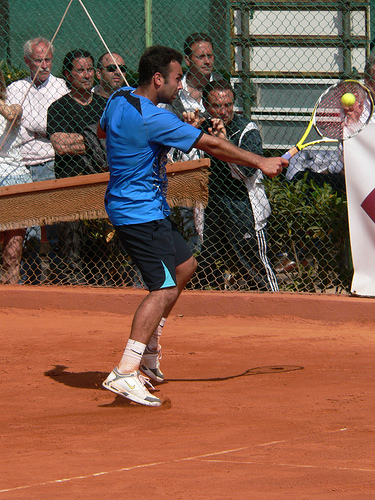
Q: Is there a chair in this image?
A: No, there are no chairs.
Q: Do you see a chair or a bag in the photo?
A: No, there are no chairs or bags.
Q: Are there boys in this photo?
A: No, there are no boys.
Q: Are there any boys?
A: No, there are no boys.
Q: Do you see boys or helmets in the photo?
A: No, there are no boys or helmets.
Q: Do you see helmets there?
A: No, there are no helmets.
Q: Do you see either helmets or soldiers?
A: No, there are no helmets or soldiers.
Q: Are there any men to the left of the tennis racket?
A: Yes, there is a man to the left of the tennis racket.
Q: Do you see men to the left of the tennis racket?
A: Yes, there is a man to the left of the tennis racket.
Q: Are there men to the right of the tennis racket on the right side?
A: No, the man is to the left of the racket.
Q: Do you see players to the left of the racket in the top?
A: No, there is a man to the left of the racket.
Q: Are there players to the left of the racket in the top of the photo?
A: No, there is a man to the left of the racket.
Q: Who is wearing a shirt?
A: The man is wearing a shirt.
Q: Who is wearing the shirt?
A: The man is wearing a shirt.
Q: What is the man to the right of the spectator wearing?
A: The man is wearing a shirt.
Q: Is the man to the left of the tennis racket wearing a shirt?
A: Yes, the man is wearing a shirt.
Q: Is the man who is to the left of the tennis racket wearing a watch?
A: No, the man is wearing a shirt.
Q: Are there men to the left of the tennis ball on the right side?
A: Yes, there is a man to the left of the tennis ball.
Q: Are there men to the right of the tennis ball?
A: No, the man is to the left of the tennis ball.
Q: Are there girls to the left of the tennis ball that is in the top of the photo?
A: No, there is a man to the left of the tennis ball.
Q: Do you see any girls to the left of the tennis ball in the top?
A: No, there is a man to the left of the tennis ball.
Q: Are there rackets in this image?
A: Yes, there is a racket.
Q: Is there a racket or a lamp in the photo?
A: Yes, there is a racket.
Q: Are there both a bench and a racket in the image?
A: No, there is a racket but no benches.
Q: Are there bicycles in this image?
A: No, there are no bicycles.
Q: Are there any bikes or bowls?
A: No, there are no bikes or bowls.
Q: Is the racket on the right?
A: Yes, the racket is on the right of the image.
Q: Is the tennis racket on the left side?
A: No, the tennis racket is on the right of the image.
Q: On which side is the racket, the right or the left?
A: The racket is on the right of the image.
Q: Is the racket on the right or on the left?
A: The racket is on the right of the image.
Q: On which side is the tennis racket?
A: The tennis racket is on the right of the image.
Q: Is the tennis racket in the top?
A: Yes, the tennis racket is in the top of the image.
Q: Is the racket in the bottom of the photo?
A: No, the racket is in the top of the image.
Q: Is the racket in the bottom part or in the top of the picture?
A: The racket is in the top of the image.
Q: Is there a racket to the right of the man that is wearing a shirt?
A: Yes, there is a racket to the right of the man.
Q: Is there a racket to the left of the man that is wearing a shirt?
A: No, the racket is to the right of the man.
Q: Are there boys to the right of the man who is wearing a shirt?
A: No, there is a racket to the right of the man.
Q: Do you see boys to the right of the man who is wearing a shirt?
A: No, there is a racket to the right of the man.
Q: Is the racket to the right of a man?
A: Yes, the racket is to the right of a man.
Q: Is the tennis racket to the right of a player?
A: No, the tennis racket is to the right of a man.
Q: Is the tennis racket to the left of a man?
A: No, the tennis racket is to the right of a man.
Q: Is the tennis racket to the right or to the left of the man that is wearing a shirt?
A: The tennis racket is to the right of the man.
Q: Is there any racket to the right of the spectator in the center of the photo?
A: Yes, there is a racket to the right of the spectator.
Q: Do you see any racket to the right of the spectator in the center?
A: Yes, there is a racket to the right of the spectator.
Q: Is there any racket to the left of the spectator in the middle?
A: No, the racket is to the right of the spectator.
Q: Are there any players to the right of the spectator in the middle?
A: No, there is a racket to the right of the spectator.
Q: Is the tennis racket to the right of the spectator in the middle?
A: Yes, the tennis racket is to the right of the spectator.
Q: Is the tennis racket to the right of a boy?
A: No, the tennis racket is to the right of the spectator.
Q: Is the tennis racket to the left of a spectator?
A: No, the tennis racket is to the right of a spectator.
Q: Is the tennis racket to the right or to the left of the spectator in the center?
A: The tennis racket is to the right of the spectator.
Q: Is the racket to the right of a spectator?
A: Yes, the racket is to the right of a spectator.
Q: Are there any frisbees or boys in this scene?
A: No, there are no boys or frisbees.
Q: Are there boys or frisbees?
A: No, there are no boys or frisbees.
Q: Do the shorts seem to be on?
A: Yes, the shorts are on.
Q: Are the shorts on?
A: Yes, the shorts are on.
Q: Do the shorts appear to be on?
A: Yes, the shorts are on.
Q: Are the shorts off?
A: No, the shorts are on.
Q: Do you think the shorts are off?
A: No, the shorts are on.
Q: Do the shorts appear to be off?
A: No, the shorts are on.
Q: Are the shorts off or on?
A: The shorts are on.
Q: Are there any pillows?
A: No, there are no pillows.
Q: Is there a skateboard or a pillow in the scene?
A: No, there are no pillows or skateboards.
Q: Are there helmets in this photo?
A: No, there are no helmets.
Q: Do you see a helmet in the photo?
A: No, there are no helmets.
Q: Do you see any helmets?
A: No, there are no helmets.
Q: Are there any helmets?
A: No, there are no helmets.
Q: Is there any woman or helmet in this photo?
A: No, there are no helmets or women.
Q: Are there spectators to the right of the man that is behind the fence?
A: Yes, there is a spectator to the right of the man.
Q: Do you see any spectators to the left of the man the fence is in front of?
A: No, the spectator is to the right of the man.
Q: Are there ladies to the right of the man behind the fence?
A: No, there is a spectator to the right of the man.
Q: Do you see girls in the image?
A: No, there are no girls.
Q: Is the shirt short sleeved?
A: Yes, the shirt is short sleeved.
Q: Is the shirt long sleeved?
A: No, the shirt is short sleeved.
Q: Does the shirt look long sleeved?
A: No, the shirt is short sleeved.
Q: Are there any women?
A: No, there are no women.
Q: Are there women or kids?
A: No, there are no women or kids.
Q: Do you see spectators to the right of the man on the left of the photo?
A: Yes, there is a spectator to the right of the man.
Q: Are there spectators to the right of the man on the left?
A: Yes, there is a spectator to the right of the man.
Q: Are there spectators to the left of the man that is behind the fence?
A: No, the spectator is to the right of the man.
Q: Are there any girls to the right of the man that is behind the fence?
A: No, there is a spectator to the right of the man.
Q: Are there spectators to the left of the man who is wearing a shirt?
A: Yes, there is a spectator to the left of the man.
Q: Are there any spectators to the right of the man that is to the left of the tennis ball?
A: No, the spectator is to the left of the man.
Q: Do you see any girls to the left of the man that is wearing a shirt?
A: No, there is a spectator to the left of the man.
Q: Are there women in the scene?
A: No, there are no women.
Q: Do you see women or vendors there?
A: No, there are no women or vendors.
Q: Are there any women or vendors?
A: No, there are no women or vendors.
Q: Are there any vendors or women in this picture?
A: No, there are no women or vendors.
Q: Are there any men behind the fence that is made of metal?
A: Yes, there is a man behind the fence.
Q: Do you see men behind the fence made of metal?
A: Yes, there is a man behind the fence.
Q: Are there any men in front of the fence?
A: No, the man is behind the fence.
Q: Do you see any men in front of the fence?
A: No, the man is behind the fence.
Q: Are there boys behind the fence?
A: No, there is a man behind the fence.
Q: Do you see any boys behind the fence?
A: No, there is a man behind the fence.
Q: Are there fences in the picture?
A: Yes, there is a fence.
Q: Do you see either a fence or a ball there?
A: Yes, there is a fence.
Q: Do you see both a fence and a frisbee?
A: No, there is a fence but no frisbees.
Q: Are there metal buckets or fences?
A: Yes, there is a metal fence.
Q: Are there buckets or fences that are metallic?
A: Yes, the fence is metallic.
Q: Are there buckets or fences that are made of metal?
A: Yes, the fence is made of metal.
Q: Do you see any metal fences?
A: Yes, there is a metal fence.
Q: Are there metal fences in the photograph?
A: Yes, there is a metal fence.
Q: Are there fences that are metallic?
A: Yes, there is a fence that is metallic.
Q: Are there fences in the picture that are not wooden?
A: Yes, there is a metallic fence.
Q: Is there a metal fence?
A: Yes, there is a fence that is made of metal.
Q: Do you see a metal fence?
A: Yes, there is a fence that is made of metal.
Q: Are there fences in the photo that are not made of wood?
A: Yes, there is a fence that is made of metal.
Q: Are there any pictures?
A: No, there are no pictures.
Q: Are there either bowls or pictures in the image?
A: No, there are no pictures or bowls.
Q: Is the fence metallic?
A: Yes, the fence is metallic.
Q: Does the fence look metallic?
A: Yes, the fence is metallic.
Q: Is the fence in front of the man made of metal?
A: Yes, the fence is made of metal.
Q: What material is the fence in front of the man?
A: The fence is made of metal.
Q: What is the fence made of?
A: The fence is made of metal.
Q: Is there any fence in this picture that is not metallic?
A: No, there is a fence but it is metallic.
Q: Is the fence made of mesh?
A: No, the fence is made of metal.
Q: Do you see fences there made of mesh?
A: No, there is a fence but it is made of metal.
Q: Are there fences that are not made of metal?
A: No, there is a fence but it is made of metal.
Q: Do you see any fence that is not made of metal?
A: No, there is a fence but it is made of metal.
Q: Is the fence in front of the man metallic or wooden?
A: The fence is metallic.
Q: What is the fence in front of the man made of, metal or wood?
A: The fence is made of metal.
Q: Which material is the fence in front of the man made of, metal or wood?
A: The fence is made of metal.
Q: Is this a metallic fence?
A: Yes, this is a metallic fence.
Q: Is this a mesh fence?
A: No, this is a metallic fence.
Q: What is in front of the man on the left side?
A: The fence is in front of the man.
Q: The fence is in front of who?
A: The fence is in front of the man.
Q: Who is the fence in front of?
A: The fence is in front of the man.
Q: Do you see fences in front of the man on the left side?
A: Yes, there is a fence in front of the man.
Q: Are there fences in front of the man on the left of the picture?
A: Yes, there is a fence in front of the man.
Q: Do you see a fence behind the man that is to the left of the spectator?
A: No, the fence is in front of the man.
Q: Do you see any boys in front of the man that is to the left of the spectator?
A: No, there is a fence in front of the man.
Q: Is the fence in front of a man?
A: Yes, the fence is in front of a man.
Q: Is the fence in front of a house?
A: No, the fence is in front of a man.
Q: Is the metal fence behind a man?
A: No, the fence is in front of a man.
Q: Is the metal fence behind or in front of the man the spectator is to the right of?
A: The fence is in front of the man.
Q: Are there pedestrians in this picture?
A: No, there are no pedestrians.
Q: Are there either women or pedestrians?
A: No, there are no pedestrians or women.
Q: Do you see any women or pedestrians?
A: No, there are no pedestrians or women.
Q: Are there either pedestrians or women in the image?
A: No, there are no pedestrians or women.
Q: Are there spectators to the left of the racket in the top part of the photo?
A: Yes, there is a spectator to the left of the racket.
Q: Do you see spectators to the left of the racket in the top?
A: Yes, there is a spectator to the left of the racket.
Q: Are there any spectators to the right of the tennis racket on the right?
A: No, the spectator is to the left of the tennis racket.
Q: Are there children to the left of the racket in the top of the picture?
A: No, there is a spectator to the left of the tennis racket.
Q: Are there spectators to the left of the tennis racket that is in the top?
A: Yes, there is a spectator to the left of the tennis racket.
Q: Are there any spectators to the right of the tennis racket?
A: No, the spectator is to the left of the tennis racket.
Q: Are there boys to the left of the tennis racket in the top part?
A: No, there is a spectator to the left of the tennis racket.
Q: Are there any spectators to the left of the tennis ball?
A: Yes, there is a spectator to the left of the tennis ball.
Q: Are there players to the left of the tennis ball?
A: No, there is a spectator to the left of the tennis ball.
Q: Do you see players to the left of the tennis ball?
A: No, there is a spectator to the left of the tennis ball.